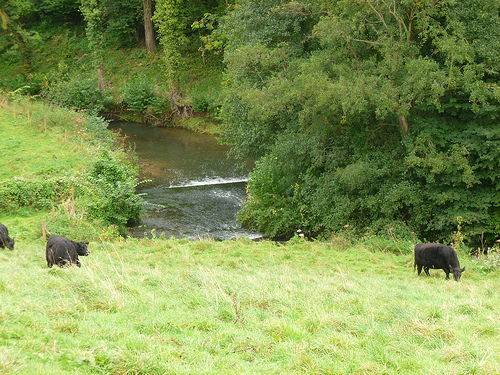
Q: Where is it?
A: This is at the forest.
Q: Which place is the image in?
A: It is at the forest.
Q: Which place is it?
A: It is a forest.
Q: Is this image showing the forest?
A: Yes, it is showing the forest.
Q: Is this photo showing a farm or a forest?
A: It is showing a forest.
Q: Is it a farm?
A: No, it is a forest.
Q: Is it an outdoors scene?
A: Yes, it is outdoors.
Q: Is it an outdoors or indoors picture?
A: It is outdoors.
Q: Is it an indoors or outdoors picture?
A: It is outdoors.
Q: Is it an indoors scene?
A: No, it is outdoors.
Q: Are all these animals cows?
A: Yes, all the animals are cows.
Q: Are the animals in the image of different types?
A: No, all the animals are cows.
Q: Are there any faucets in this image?
A: No, there are no faucets.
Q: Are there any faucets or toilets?
A: No, there are no faucets or toilets.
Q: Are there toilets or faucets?
A: No, there are no faucets or toilets.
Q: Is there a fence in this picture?
A: No, there are no fences.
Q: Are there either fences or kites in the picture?
A: No, there are no fences or kites.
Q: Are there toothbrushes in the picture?
A: No, there are no toothbrushes.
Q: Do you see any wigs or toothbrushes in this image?
A: No, there are no toothbrushes or wigs.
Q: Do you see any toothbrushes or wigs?
A: No, there are no toothbrushes or wigs.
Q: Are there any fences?
A: No, there are no fences.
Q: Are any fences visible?
A: No, there are no fences.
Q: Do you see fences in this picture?
A: No, there are no fences.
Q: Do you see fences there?
A: No, there are no fences.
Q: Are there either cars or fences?
A: No, there are no fences or cars.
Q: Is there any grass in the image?
A: Yes, there is grass.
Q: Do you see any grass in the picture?
A: Yes, there is grass.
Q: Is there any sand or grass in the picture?
A: Yes, there is grass.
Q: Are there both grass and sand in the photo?
A: No, there is grass but no sand.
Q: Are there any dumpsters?
A: No, there are no dumpsters.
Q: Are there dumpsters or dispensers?
A: No, there are no dumpsters or dispensers.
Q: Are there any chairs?
A: No, there are no chairs.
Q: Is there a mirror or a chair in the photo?
A: No, there are no chairs or mirrors.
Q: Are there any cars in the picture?
A: No, there are no cars.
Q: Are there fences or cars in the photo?
A: No, there are no cars or fences.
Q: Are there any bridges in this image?
A: No, there are no bridges.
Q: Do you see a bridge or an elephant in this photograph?
A: No, there are no bridges or elephants.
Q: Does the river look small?
A: Yes, the river is small.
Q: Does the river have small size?
A: Yes, the river is small.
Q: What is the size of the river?
A: The river is small.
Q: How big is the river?
A: The river is small.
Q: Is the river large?
A: No, the river is small.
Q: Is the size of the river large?
A: No, the river is small.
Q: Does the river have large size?
A: No, the river is small.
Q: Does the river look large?
A: No, the river is small.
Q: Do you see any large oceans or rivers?
A: No, there is a river but it is small.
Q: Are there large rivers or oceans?
A: No, there is a river but it is small.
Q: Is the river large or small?
A: The river is small.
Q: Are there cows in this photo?
A: Yes, there is a cow.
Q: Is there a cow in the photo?
A: Yes, there is a cow.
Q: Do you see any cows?
A: Yes, there is a cow.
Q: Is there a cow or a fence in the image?
A: Yes, there is a cow.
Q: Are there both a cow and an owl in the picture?
A: No, there is a cow but no owls.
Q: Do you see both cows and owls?
A: No, there is a cow but no owls.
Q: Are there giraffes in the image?
A: No, there are no giraffes.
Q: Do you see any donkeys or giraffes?
A: No, there are no giraffes or donkeys.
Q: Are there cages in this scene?
A: No, there are no cages.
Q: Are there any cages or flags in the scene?
A: No, there are no cages or flags.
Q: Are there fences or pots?
A: No, there are no fences or pots.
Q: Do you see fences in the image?
A: No, there are no fences.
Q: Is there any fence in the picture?
A: No, there are no fences.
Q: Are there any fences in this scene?
A: No, there are no fences.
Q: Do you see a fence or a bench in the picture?
A: No, there are no fences or benches.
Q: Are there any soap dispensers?
A: No, there are no soap dispensers.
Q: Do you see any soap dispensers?
A: No, there are no soap dispensers.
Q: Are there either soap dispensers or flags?
A: No, there are no soap dispensers or flags.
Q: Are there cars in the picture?
A: No, there are no cars.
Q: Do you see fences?
A: No, there are no fences.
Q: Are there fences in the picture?
A: No, there are no fences.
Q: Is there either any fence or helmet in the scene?
A: No, there are no fences or helmets.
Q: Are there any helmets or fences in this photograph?
A: No, there are no fences or helmets.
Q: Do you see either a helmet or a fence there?
A: No, there are no fences or helmets.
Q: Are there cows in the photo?
A: Yes, there is a cow.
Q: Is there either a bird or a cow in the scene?
A: Yes, there is a cow.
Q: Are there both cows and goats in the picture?
A: No, there is a cow but no goats.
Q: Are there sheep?
A: No, there are no sheep.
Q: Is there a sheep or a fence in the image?
A: No, there are no sheep or fences.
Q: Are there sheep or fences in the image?
A: No, there are no sheep or fences.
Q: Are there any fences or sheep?
A: No, there are no sheep or fences.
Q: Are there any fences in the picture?
A: No, there are no fences.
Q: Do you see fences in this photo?
A: No, there are no fences.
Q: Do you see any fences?
A: No, there are no fences.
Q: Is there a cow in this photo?
A: Yes, there is a cow.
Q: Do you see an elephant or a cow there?
A: Yes, there is a cow.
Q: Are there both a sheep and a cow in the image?
A: No, there is a cow but no sheep.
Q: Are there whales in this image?
A: No, there are no whales.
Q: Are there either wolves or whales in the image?
A: No, there are no whales or wolves.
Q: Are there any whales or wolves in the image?
A: No, there are no whales or wolves.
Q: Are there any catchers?
A: No, there are no catchers.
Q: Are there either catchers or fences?
A: No, there are no catchers or fences.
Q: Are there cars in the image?
A: No, there are no cars.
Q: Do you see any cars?
A: No, there are no cars.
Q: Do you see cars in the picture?
A: No, there are no cars.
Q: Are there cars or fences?
A: No, there are no cars or fences.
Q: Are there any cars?
A: No, there are no cars.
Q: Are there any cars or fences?
A: No, there are no cars or fences.